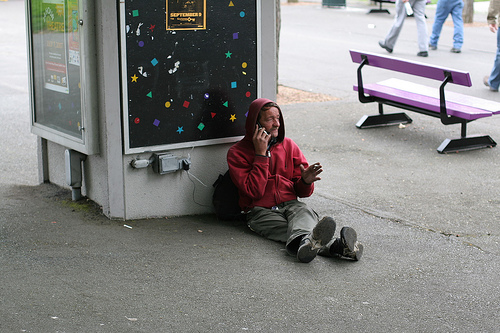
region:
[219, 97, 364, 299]
a man sittin gon the ground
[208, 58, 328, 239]
a man wearing a hoodie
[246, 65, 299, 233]
a man wearing a red hoodie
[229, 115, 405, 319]
a man wearing pants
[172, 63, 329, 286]
a man sitting against pole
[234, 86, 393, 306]
a man on a phone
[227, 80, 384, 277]
A man is sitting on the floor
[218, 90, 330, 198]
The man is wearing red hoodie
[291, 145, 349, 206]
The man is holding a cigarette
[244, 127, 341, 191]
The man is holding two cigarettes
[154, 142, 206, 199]
The phone is plugged into an outlet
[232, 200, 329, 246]
The man is wearing a olive pant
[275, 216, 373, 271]
The man is wearing a pair of shoes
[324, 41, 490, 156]
The bench in the picture is purple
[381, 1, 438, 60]
A man is holding a bottle of water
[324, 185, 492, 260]
The crack in the street is large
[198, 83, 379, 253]
man on the ground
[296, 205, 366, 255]
feet of the man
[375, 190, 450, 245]
line on the ground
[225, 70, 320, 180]
sweatshirt on the man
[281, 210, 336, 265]
shoe of the man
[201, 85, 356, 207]
man talking on a phone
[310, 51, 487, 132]
purple bench on ground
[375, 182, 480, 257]
crack in the ground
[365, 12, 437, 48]
legs of the man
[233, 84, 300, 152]
hood on man's head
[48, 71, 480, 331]
the man is homeless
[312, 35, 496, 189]
this is a bus stop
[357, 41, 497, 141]
the bench is pink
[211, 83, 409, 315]
the man is sitting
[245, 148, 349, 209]
the jacket is red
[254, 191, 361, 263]
the pants are gray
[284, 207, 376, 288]
the shoes are black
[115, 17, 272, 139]
the poster is black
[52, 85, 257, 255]
the post is gray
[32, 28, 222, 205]
the post is large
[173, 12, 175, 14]
a letter is written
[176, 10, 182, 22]
a letter is written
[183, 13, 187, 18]
a letter is written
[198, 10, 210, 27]
a letter is written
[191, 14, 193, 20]
a letter is written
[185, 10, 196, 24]
a letter is written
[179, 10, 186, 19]
a letter is written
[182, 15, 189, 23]
a letter is written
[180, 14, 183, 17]
a letter is written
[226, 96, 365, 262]
Man in red hoodie and grey pants.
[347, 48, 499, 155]
A purple bench.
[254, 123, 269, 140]
Silver cellphone a man is talking on.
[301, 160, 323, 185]
Man sitting down's left hand.